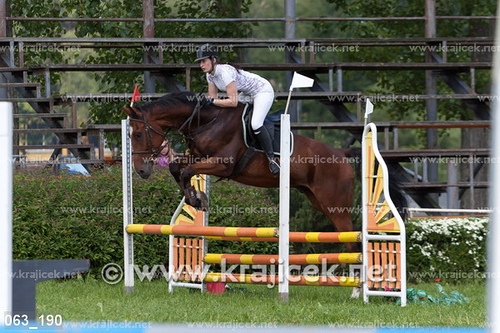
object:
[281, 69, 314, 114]
flags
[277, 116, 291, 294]
poles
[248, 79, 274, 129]
pants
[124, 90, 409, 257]
horse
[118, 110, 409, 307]
obstacle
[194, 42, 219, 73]
head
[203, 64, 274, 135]
jockey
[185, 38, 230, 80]
face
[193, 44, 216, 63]
helmet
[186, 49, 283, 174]
woman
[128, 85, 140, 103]
flag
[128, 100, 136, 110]
pole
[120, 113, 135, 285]
poles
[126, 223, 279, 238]
poles